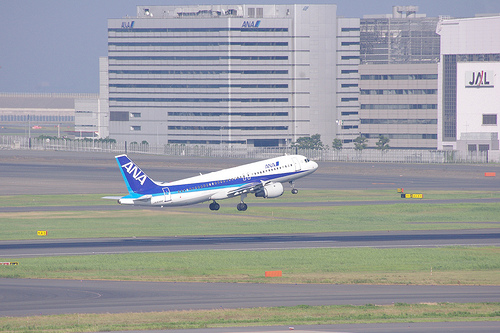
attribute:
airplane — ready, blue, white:
[105, 143, 322, 213]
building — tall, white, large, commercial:
[102, 4, 343, 143]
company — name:
[119, 160, 148, 189]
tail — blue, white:
[116, 150, 158, 193]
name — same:
[237, 18, 263, 31]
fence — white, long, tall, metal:
[0, 131, 497, 167]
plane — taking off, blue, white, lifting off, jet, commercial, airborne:
[99, 140, 323, 216]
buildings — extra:
[340, 9, 499, 149]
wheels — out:
[209, 200, 251, 214]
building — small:
[74, 56, 110, 132]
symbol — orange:
[265, 268, 284, 278]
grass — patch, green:
[1, 240, 499, 282]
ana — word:
[120, 156, 148, 186]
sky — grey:
[1, 0, 500, 91]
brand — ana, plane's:
[122, 156, 153, 191]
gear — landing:
[205, 202, 250, 214]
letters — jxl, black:
[464, 71, 494, 90]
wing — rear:
[99, 194, 122, 201]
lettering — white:
[123, 158, 151, 188]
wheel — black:
[216, 202, 221, 213]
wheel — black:
[206, 199, 214, 210]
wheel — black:
[242, 202, 248, 210]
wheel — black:
[237, 203, 242, 210]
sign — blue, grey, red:
[467, 69, 495, 89]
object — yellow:
[401, 191, 428, 199]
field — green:
[5, 183, 496, 329]